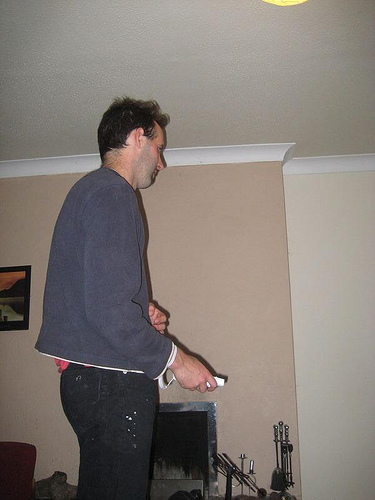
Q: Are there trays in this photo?
A: No, there are no trays.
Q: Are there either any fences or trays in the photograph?
A: No, there are no trays or fences.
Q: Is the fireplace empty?
A: Yes, the fireplace is empty.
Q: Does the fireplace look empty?
A: Yes, the fireplace is empty.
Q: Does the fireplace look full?
A: No, the fireplace is empty.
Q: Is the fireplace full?
A: No, the fireplace is empty.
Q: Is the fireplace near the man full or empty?
A: The fireplace is empty.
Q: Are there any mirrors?
A: No, there are no mirrors.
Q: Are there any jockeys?
A: No, there are no jockeys.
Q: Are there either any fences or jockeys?
A: No, there are no jockeys or fences.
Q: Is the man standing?
A: Yes, the man is standing.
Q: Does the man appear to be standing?
A: Yes, the man is standing.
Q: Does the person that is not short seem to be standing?
A: Yes, the man is standing.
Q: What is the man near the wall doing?
A: The man is standing.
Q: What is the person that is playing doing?
A: The man is standing.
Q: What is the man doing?
A: The man is standing.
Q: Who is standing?
A: The man is standing.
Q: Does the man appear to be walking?
A: No, the man is standing.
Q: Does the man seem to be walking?
A: No, the man is standing.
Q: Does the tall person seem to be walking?
A: No, the man is standing.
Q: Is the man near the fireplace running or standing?
A: The man is standing.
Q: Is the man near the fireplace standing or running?
A: The man is standing.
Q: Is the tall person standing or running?
A: The man is standing.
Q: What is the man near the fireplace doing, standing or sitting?
A: The man is standing.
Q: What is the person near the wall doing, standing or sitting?
A: The man is standing.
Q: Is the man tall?
A: Yes, the man is tall.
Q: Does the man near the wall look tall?
A: Yes, the man is tall.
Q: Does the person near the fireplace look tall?
A: Yes, the man is tall.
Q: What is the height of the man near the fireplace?
A: The man is tall.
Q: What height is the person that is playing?
A: The man is tall.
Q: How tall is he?
A: The man is tall.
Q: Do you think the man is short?
A: No, the man is tall.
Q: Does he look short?
A: No, the man is tall.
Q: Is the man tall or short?
A: The man is tall.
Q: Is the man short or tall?
A: The man is tall.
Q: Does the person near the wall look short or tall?
A: The man is tall.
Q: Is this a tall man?
A: Yes, this is a tall man.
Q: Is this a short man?
A: No, this is a tall man.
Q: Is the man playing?
A: Yes, the man is playing.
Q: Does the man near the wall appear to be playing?
A: Yes, the man is playing.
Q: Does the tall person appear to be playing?
A: Yes, the man is playing.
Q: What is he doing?
A: The man is playing.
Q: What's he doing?
A: The man is playing.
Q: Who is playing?
A: The man is playing.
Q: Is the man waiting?
A: No, the man is playing.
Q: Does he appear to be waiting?
A: No, the man is playing.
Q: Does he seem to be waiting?
A: No, the man is playing.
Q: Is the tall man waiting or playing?
A: The man is playing.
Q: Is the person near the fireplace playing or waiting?
A: The man is playing.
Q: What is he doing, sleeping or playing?
A: The man is playing.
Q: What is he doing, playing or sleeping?
A: The man is playing.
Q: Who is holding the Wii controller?
A: The man is holding the Wii controller.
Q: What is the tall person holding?
A: The man is holding the Wii controller.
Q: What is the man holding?
A: The man is holding the Wii controller.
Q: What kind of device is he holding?
A: The man is holding the Wii controller.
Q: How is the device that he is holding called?
A: The device is a Wii controller.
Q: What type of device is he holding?
A: The man is holding the Wii controller.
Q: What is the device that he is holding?
A: The device is a Wii controller.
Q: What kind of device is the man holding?
A: The man is holding the Wii controller.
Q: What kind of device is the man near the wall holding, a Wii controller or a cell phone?
A: The man is holding a Wii controller.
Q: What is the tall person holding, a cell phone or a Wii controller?
A: The man is holding a Wii controller.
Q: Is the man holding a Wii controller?
A: Yes, the man is holding a Wii controller.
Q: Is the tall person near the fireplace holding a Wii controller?
A: Yes, the man is holding a Wii controller.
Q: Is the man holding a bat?
A: No, the man is holding a Wii controller.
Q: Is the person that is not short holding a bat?
A: No, the man is holding a Wii controller.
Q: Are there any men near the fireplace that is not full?
A: Yes, there is a man near the fireplace.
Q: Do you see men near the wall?
A: Yes, there is a man near the wall.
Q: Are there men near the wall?
A: Yes, there is a man near the wall.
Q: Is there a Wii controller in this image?
A: Yes, there is a Wii controller.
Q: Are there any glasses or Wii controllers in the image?
A: Yes, there is a Wii controller.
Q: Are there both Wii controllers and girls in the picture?
A: No, there is a Wii controller but no girls.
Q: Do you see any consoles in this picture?
A: No, there are no consoles.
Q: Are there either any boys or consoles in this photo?
A: No, there are no consoles or boys.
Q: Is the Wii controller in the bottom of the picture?
A: Yes, the Wii controller is in the bottom of the image.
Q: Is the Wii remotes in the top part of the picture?
A: No, the Wii remotes is in the bottom of the image.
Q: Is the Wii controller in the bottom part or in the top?
A: The Wii controller is in the bottom of the image.